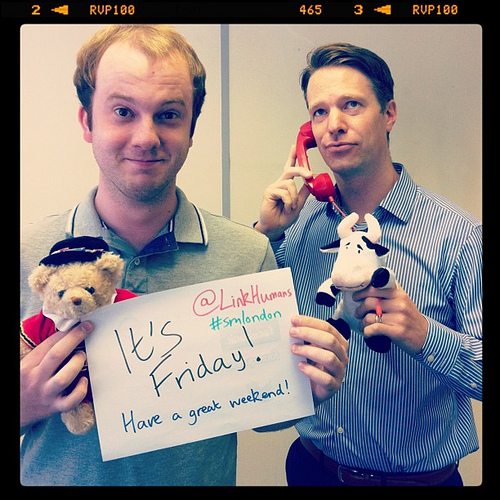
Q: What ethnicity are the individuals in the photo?
A: Caucasian.